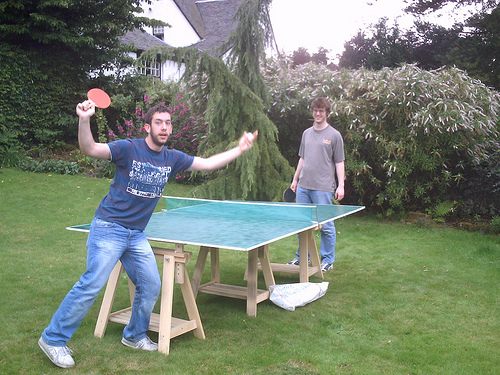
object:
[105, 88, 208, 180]
bush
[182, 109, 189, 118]
flowers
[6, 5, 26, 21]
leaves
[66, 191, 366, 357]
table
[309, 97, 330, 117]
hair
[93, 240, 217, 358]
saw horse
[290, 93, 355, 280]
man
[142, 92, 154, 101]
flowers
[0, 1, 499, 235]
bush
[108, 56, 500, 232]
bush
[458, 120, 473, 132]
flowers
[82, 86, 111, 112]
paddle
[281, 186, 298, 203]
paddle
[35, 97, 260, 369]
man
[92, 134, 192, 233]
shirt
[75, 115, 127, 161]
arm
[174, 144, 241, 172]
arm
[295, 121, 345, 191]
shirt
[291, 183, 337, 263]
jeans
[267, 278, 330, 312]
bag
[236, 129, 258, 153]
hand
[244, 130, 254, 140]
ball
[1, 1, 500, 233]
tree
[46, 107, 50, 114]
leaf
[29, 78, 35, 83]
leaf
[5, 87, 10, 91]
leaf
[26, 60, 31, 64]
leaf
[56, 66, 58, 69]
leaf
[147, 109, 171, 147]
face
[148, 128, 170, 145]
beard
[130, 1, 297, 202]
evergreen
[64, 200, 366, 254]
table top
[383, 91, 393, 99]
flower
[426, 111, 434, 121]
flower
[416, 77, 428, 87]
flower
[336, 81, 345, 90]
flower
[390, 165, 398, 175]
flower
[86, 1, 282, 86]
house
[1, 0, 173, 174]
greenery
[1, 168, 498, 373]
grass